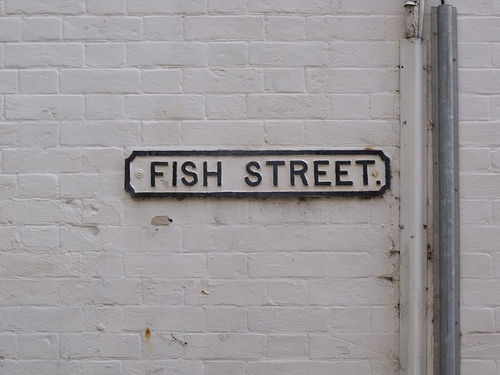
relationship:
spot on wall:
[135, 320, 159, 349] [202, 42, 383, 107]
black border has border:
[121, 148, 390, 202] [122, 146, 393, 201]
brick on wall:
[265, 284, 347, 304] [4, 6, 484, 361]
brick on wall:
[19, 14, 66, 45] [4, 6, 484, 361]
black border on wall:
[121, 148, 390, 202] [4, 6, 484, 361]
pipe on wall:
[432, 1, 462, 371] [4, 6, 484, 361]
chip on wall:
[150, 206, 180, 232] [234, 39, 375, 122]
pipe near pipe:
[432, 1, 462, 374] [399, 71, 430, 295]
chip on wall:
[150, 215, 173, 226] [4, 6, 484, 361]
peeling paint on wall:
[71, 218, 103, 240] [4, 6, 484, 361]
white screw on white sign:
[134, 166, 145, 183] [130, 155, 384, 191]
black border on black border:
[121, 136, 390, 201] [121, 148, 390, 202]